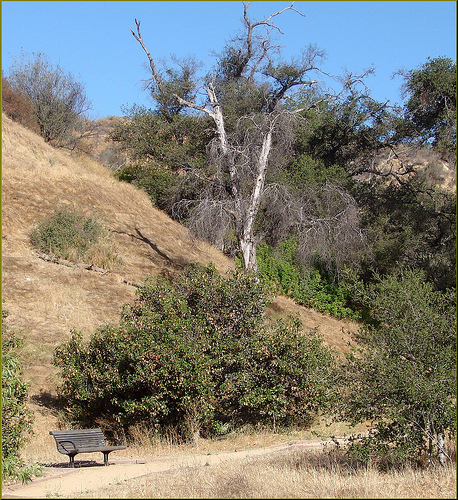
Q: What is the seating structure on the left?
A: A bench.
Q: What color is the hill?
A: Beige.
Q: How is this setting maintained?
A: By nature.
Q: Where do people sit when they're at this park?
A: On the bench.